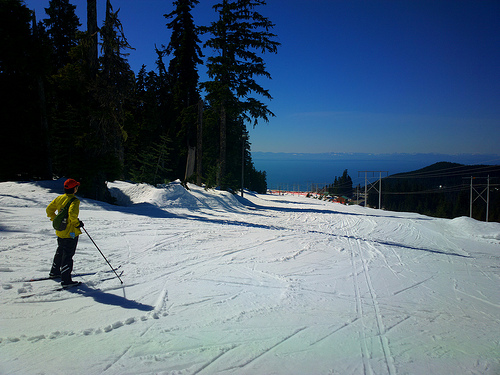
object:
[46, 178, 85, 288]
skier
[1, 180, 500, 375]
field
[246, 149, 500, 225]
mountains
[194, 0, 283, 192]
trees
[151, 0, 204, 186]
trees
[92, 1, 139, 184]
trees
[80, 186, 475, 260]
shadow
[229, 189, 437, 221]
shadow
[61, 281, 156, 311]
shadow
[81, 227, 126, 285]
pole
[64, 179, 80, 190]
cap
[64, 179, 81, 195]
head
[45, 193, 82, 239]
coat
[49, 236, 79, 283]
pants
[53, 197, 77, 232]
bag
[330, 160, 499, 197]
lines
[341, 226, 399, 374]
tracks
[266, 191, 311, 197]
fence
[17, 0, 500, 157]
sky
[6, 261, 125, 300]
skis